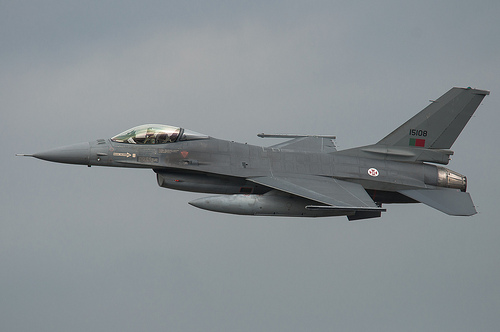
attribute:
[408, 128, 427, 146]
markings — Green, red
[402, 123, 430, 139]
number — 15108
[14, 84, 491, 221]
plane — pointy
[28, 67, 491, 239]
airplane — large, grey, military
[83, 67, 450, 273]
aircraft — military style